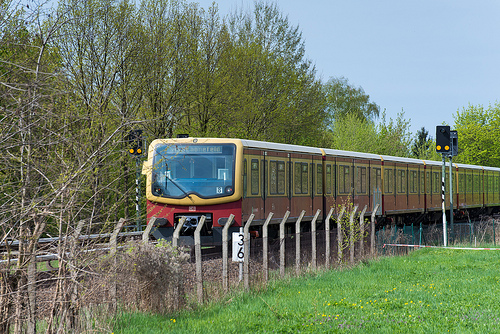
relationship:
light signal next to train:
[430, 125, 452, 153] [146, 134, 499, 249]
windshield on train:
[153, 140, 228, 197] [146, 134, 499, 249]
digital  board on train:
[164, 141, 225, 157] [146, 134, 499, 249]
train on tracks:
[146, 134, 499, 249] [10, 212, 487, 296]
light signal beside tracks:
[430, 125, 452, 153] [10, 212, 487, 296]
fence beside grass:
[7, 196, 497, 334] [168, 248, 499, 333]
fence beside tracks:
[7, 196, 497, 334] [10, 212, 487, 296]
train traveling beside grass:
[146, 134, 499, 249] [168, 248, 499, 333]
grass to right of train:
[168, 248, 499, 333] [146, 134, 499, 249]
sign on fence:
[233, 231, 248, 265] [7, 196, 497, 334]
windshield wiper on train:
[162, 176, 196, 202] [146, 134, 499, 249]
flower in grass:
[327, 299, 331, 309] [168, 248, 499, 333]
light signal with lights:
[430, 125, 452, 153] [437, 145, 451, 153]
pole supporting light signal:
[439, 160, 450, 249] [430, 125, 452, 153]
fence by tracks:
[7, 196, 497, 334] [10, 212, 487, 296]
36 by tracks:
[235, 232, 246, 261] [10, 212, 487, 296]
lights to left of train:
[437, 145, 451, 153] [146, 134, 499, 249]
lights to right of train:
[437, 145, 451, 153] [146, 134, 499, 249]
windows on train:
[249, 156, 500, 195] [146, 134, 499, 249]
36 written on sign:
[235, 232, 246, 261] [233, 231, 248, 265]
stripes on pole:
[442, 182, 450, 205] [439, 160, 450, 249]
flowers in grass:
[169, 272, 485, 331] [168, 248, 499, 333]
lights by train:
[437, 145, 451, 153] [146, 134, 499, 249]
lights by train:
[127, 147, 141, 157] [146, 134, 499, 249]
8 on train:
[217, 185, 223, 196] [146, 134, 499, 249]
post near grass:
[192, 215, 206, 303] [168, 248, 499, 333]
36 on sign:
[235, 232, 246, 261] [233, 231, 248, 265]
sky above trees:
[3, 3, 498, 139] [2, 4, 500, 220]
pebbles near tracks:
[9, 225, 358, 314] [10, 212, 487, 296]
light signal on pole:
[430, 125, 452, 153] [439, 160, 450, 249]